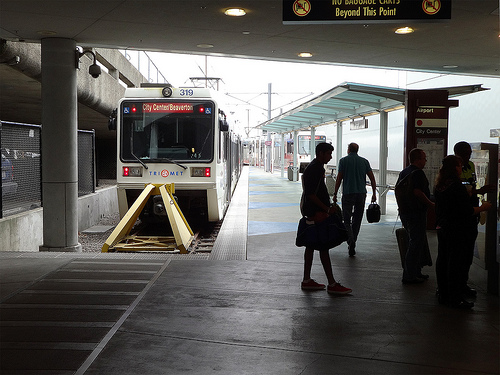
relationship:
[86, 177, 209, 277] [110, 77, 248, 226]
yellow triangle front train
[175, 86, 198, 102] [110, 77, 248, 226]
number 319 on train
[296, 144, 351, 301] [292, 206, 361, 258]
guy in red sneaker has duffel bag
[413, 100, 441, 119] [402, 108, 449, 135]
white letters says airport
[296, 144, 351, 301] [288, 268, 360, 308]
guy in red sneaker wears red sneakers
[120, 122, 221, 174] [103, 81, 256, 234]
windshield wipers front passenger train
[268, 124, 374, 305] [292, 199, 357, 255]
guy in red sneaker holds duffel bag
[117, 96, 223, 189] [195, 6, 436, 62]
illuminated lights on ceiling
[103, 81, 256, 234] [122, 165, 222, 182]
passenger train has set of two lights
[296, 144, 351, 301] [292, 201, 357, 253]
guy in red sneaker holds luggage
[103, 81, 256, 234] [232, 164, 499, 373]
passenger train in platform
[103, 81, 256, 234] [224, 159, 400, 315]
passenger train on platform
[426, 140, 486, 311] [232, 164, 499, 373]
two on platform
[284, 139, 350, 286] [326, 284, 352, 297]
man wearing tennis shoes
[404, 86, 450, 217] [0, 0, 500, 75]
sign hanging from ceiling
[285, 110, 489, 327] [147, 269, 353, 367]
several people on platform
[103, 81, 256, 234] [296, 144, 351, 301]
passenger train carrying guy in red sneaker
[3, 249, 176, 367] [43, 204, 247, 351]
crosswalk lines on concrete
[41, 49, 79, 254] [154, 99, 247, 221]
column near train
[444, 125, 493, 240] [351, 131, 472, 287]
train worker helping riders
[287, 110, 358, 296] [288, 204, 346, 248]
man carrying bags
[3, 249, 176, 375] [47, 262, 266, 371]
crosswalk lines on concrete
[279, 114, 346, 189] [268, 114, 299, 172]
car behind a fence behind fence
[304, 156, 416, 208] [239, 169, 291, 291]
black fence on concrete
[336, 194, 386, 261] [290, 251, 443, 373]
two legs in a shadow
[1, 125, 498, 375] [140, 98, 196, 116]
airport sign a white lettered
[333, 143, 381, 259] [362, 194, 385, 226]
man walking away bag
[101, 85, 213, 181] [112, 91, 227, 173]
front of train with four red lights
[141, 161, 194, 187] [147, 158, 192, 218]
tri met sign letter blue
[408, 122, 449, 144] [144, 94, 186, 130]
city center sign in white letters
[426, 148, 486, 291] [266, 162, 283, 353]
two men on train platform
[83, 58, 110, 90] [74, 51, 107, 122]
camera suspended from column